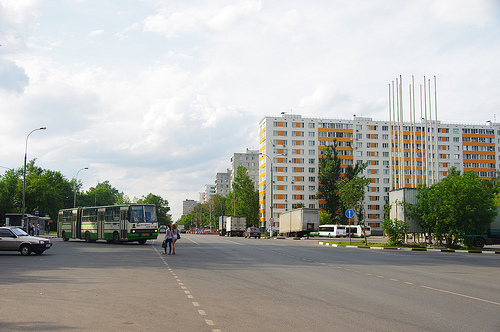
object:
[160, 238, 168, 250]
bag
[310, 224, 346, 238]
buses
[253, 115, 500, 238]
buildings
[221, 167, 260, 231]
trees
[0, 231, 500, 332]
paved road